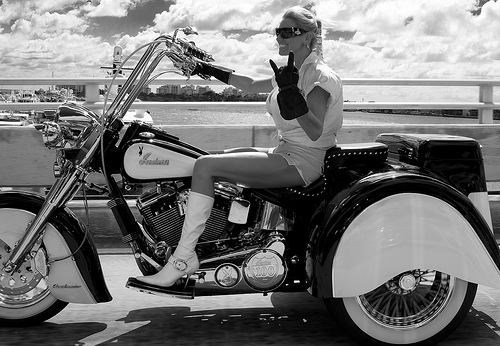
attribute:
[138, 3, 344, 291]
woman — Blond 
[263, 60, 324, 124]
gloves — black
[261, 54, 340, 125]
glove — Black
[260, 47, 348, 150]
shirt — knotted 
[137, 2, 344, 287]
babe — hot , biker 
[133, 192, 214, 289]
boots — white, knee high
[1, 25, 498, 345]
motorcycle — vintage , Indian 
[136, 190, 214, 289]
boot — white 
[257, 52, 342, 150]
top — white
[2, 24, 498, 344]
cycle — chrome, three wheel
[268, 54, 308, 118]
hand — gloved